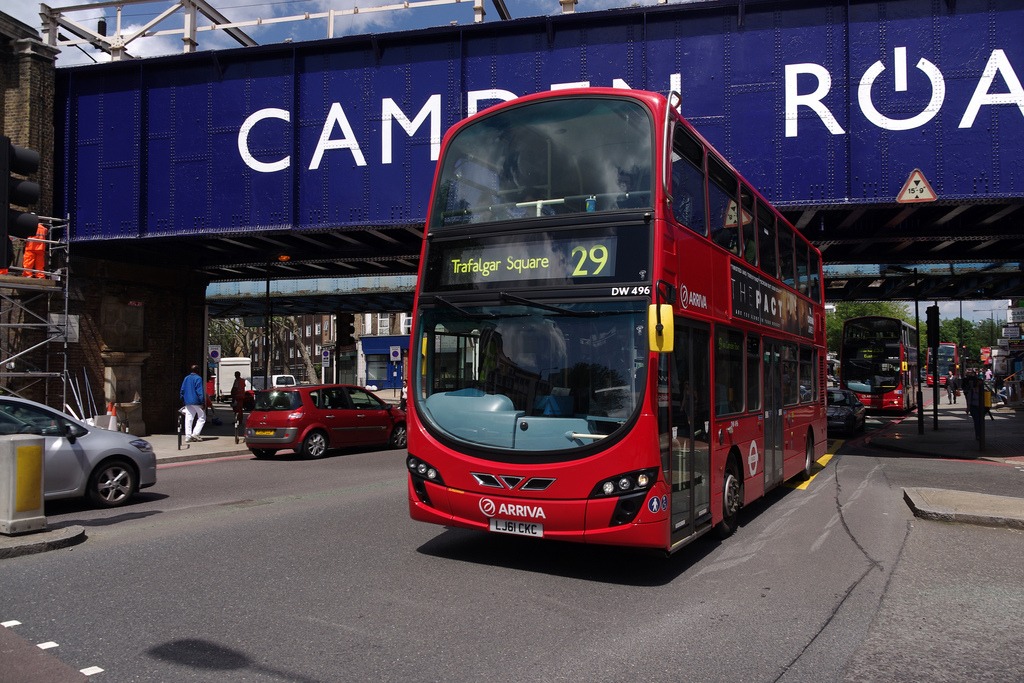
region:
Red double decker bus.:
[392, 85, 835, 575]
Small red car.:
[234, 376, 406, 454]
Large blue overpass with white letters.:
[55, 3, 1020, 267]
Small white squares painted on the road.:
[0, 612, 108, 677]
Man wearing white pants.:
[177, 358, 212, 450]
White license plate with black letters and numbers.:
[485, 509, 550, 539]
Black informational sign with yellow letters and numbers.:
[431, 224, 622, 283]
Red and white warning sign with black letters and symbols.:
[890, 167, 938, 205]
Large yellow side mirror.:
[640, 297, 683, 354]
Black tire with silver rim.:
[87, 455, 138, 506]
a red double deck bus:
[363, 62, 863, 571]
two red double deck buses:
[423, 91, 940, 572]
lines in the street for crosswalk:
[0, 594, 138, 677]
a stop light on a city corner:
[893, 301, 974, 458]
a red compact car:
[201, 361, 401, 478]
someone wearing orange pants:
[0, 230, 67, 300]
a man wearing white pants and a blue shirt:
[167, 354, 222, 453]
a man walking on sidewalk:
[160, 337, 215, 449]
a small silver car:
[15, 385, 194, 515]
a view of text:
[234, 85, 506, 199]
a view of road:
[288, 598, 426, 663]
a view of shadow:
[132, 610, 272, 675]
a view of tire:
[647, 426, 821, 567]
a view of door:
[577, 119, 775, 528]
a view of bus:
[338, 202, 877, 604]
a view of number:
[424, 461, 618, 578]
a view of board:
[72, 40, 924, 225]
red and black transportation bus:
[400, 82, 830, 569]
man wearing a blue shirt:
[174, 358, 213, 447]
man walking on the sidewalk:
[172, 358, 217, 448]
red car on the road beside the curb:
[234, 375, 402, 462]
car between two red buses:
[822, 382, 874, 444]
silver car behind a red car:
[0, 386, 162, 513]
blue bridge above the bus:
[57, 0, 1022, 285]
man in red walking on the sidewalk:
[225, 364, 249, 438]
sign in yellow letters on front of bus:
[444, 228, 622, 280]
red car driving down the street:
[238, 374, 403, 461]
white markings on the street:
[0, 607, 107, 672]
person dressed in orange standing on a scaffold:
[0, 197, 62, 425]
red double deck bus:
[405, 89, 826, 554]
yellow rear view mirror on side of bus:
[640, 277, 670, 350]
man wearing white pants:
[169, 343, 212, 439]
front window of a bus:
[405, 84, 656, 458]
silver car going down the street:
[0, 391, 160, 516]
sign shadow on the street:
[145, 631, 346, 676]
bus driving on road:
[402, 90, 848, 584]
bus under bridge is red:
[399, 82, 842, 573]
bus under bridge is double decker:
[377, 71, 837, 584]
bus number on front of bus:
[564, 235, 607, 283]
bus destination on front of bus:
[442, 249, 556, 282]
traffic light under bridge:
[918, 298, 942, 352]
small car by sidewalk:
[235, 366, 412, 468]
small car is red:
[234, 365, 415, 464]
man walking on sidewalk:
[168, 359, 214, 457]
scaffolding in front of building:
[3, 191, 87, 438]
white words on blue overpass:
[70, 4, 1022, 281]